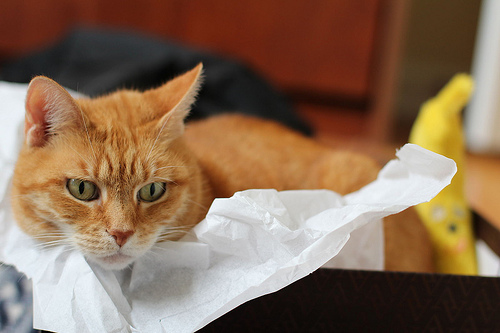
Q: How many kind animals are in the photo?
A: One.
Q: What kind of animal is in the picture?
A: Cat.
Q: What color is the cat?
A: Orange and tan.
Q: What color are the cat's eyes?
A: Yellow.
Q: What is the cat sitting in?
A: White paper.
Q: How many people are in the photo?
A: None.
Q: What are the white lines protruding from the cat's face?
A: Whiskers.